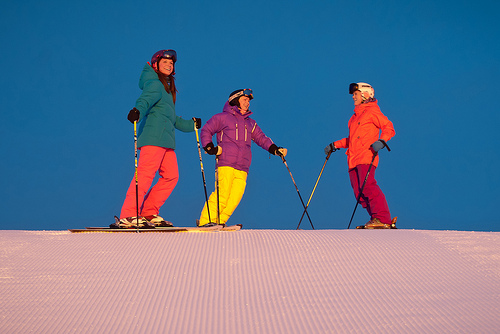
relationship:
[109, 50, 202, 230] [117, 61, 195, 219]
teenage wearing green and orange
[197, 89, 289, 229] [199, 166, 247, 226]
woman in pants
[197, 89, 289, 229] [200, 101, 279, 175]
woman in jacket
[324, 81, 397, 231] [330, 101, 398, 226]
woman in orange and purple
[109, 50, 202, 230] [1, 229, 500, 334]
teenage at top of hill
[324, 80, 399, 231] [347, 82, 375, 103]
girl has helmet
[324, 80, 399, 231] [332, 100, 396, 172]
girl has coat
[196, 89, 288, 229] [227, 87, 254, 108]
girl has helmet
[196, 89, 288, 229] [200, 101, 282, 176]
girl has coat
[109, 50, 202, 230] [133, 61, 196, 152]
teenage wearing coat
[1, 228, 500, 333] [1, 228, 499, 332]
tracks in snow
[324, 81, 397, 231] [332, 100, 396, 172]
woman wearing a coat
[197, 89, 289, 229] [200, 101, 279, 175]
woman wearing a jacket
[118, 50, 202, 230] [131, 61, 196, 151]
teenage wearing jacket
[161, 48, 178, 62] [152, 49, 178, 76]
googles on head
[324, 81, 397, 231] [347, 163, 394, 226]
woman has pants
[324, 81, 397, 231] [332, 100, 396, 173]
woman in coat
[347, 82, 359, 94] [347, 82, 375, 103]
googles on top of helmet